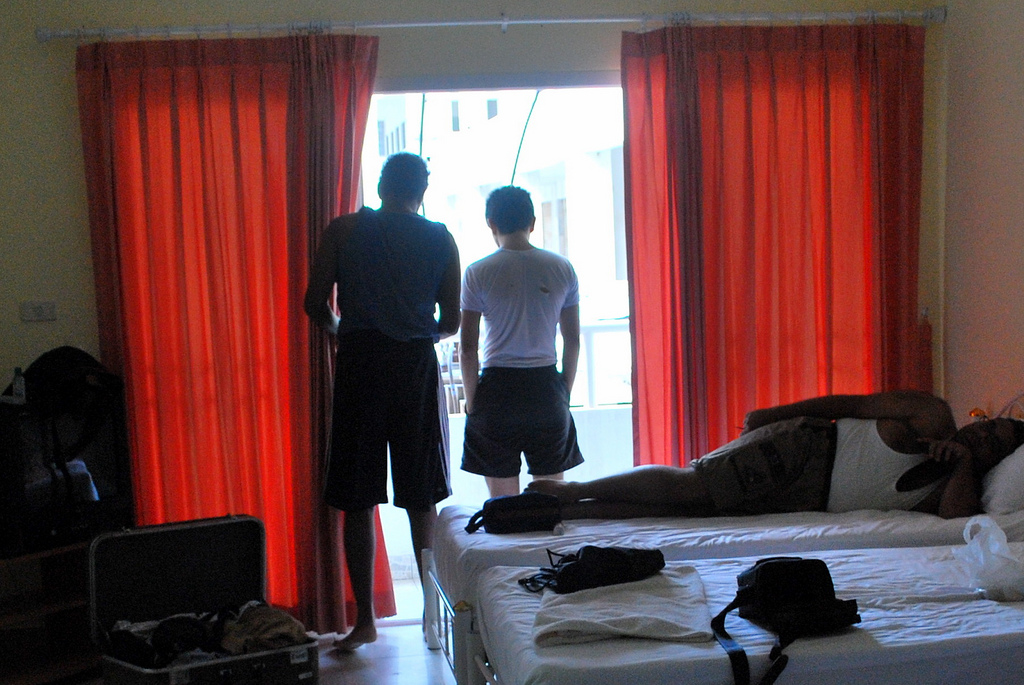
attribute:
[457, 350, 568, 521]
shorts — black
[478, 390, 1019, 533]
man — laying down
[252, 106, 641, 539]
men — young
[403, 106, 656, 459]
door way — glass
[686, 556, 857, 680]
bag — black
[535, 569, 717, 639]
towel — white 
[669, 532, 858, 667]
bag — black 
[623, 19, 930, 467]
curtain — red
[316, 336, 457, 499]
shorts — BLACK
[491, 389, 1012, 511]
man — one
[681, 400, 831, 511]
shorts — brown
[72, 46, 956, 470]
curtain — red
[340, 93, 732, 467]
window — glass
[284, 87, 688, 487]
window — glass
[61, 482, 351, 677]
suitcase — open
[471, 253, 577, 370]
shirt — white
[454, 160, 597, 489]
man — young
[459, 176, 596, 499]
man — one, young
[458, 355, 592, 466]
shorts — black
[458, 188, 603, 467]
man — young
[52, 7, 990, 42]
rod — long, white, curtain